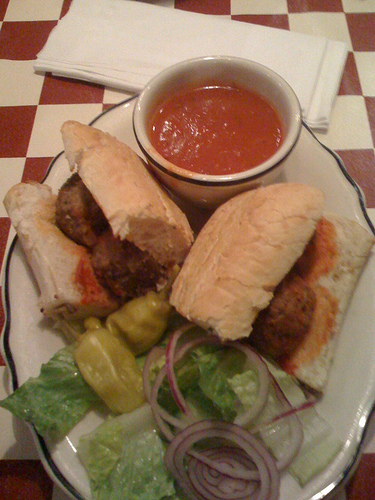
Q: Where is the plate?
A: On the table.